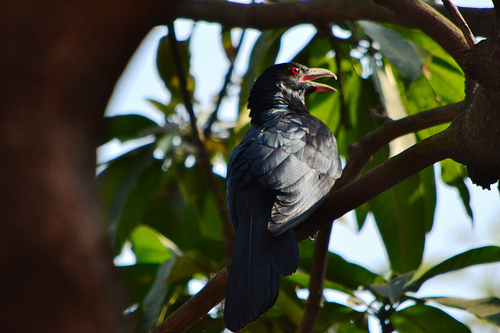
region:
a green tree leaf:
[99, 107, 157, 142]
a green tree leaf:
[145, 244, 181, 320]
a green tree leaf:
[293, 248, 352, 291]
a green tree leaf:
[373, 160, 430, 278]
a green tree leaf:
[410, 238, 482, 288]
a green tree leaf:
[156, 22, 200, 114]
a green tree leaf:
[367, 49, 426, 259]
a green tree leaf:
[131, 220, 176, 282]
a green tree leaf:
[357, 17, 421, 82]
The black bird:
[214, 51, 342, 332]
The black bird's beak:
[304, 61, 344, 99]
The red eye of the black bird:
[288, 64, 302, 76]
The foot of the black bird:
[308, 228, 318, 243]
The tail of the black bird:
[223, 220, 290, 330]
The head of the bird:
[240, 58, 314, 110]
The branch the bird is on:
[147, 131, 448, 331]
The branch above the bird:
[168, 0, 466, 65]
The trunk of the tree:
[2, 1, 157, 330]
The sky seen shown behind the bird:
[98, 6, 254, 313]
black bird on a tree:
[70, 25, 456, 316]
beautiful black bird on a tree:
[60, 30, 437, 310]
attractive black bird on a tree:
[111, 37, 408, 312]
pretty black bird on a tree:
[105, 31, 420, 306]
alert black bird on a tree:
[77, 25, 427, 315]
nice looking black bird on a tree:
[95, 11, 430, 307]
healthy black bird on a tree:
[115, 21, 400, 327]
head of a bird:
[240, 46, 340, 102]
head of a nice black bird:
[225, 40, 345, 110]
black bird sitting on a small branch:
[165, 31, 380, 326]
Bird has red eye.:
[278, 65, 302, 85]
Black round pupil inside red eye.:
[293, 63, 318, 103]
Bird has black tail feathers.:
[216, 254, 278, 312]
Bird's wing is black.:
[244, 146, 332, 241]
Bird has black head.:
[271, 72, 293, 105]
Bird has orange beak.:
[300, 40, 354, 145]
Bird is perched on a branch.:
[230, 175, 327, 285]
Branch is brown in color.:
[193, 186, 319, 285]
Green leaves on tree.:
[182, 115, 348, 322]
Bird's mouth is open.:
[274, 52, 399, 156]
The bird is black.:
[233, 53, 324, 300]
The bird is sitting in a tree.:
[216, 58, 326, 266]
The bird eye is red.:
[290, 61, 301, 85]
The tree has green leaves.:
[110, 61, 245, 211]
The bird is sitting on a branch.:
[234, 81, 364, 229]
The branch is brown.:
[373, 116, 471, 208]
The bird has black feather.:
[256, 116, 332, 185]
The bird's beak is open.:
[300, 61, 337, 101]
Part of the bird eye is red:
[282, 56, 314, 85]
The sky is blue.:
[356, 189, 493, 288]